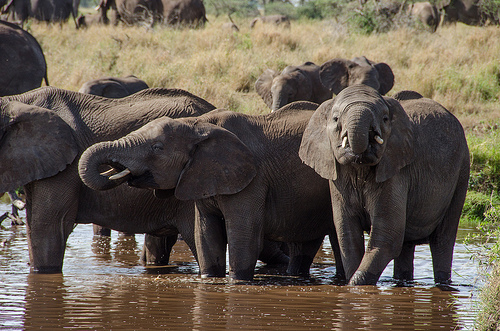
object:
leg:
[217, 191, 266, 281]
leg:
[330, 194, 368, 281]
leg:
[347, 190, 409, 285]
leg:
[392, 240, 417, 279]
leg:
[428, 225, 459, 283]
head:
[297, 82, 420, 184]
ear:
[298, 98, 342, 182]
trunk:
[77, 140, 138, 193]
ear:
[175, 124, 260, 203]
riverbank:
[0, 17, 500, 224]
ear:
[0, 100, 80, 197]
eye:
[151, 142, 166, 154]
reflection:
[393, 287, 458, 330]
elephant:
[298, 84, 475, 288]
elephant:
[0, 84, 218, 274]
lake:
[0, 204, 495, 330]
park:
[1, 1, 500, 330]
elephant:
[77, 99, 345, 280]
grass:
[430, 60, 500, 102]